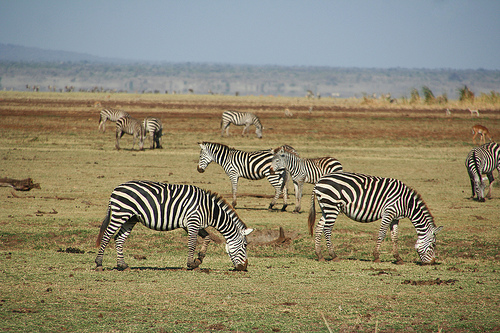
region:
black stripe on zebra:
[108, 211, 130, 222]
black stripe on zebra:
[111, 191, 148, 226]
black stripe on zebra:
[210, 202, 221, 229]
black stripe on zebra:
[218, 210, 225, 230]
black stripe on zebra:
[321, 204, 338, 211]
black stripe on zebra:
[316, 193, 341, 208]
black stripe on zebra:
[314, 180, 336, 201]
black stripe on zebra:
[406, 190, 414, 215]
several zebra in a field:
[46, 69, 468, 299]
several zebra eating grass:
[73, 77, 467, 304]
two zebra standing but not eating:
[158, 122, 388, 229]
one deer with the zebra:
[466, 108, 498, 167]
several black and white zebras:
[71, 97, 485, 288]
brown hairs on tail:
[305, 205, 319, 238]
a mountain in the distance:
[11, 38, 120, 95]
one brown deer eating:
[463, 119, 498, 156]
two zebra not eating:
[193, 128, 361, 239]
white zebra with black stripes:
[80, 167, 286, 294]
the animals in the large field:
[95, 106, 496, 268]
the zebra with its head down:
[307, 170, 442, 264]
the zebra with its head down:
[220, 109, 262, 139]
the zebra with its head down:
[465, 143, 499, 202]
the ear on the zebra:
[240, 228, 255, 235]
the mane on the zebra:
[202, 187, 247, 229]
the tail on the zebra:
[94, 193, 111, 248]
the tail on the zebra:
[306, 184, 315, 237]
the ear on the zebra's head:
[432, 225, 443, 235]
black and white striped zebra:
[93, 168, 257, 280]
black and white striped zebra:
[135, 103, 165, 148]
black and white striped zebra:
[78, 83, 124, 137]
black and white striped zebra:
[195, 99, 274, 143]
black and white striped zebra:
[189, 133, 304, 192]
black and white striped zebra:
[457, 116, 499, 188]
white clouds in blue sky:
[26, 15, 63, 41]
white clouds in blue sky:
[364, 6, 430, 60]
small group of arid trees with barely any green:
[407, 81, 476, 106]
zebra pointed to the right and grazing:
[305, 168, 440, 265]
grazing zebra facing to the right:
[92, 177, 254, 275]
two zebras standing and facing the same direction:
[193, 138, 343, 210]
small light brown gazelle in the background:
[467, 121, 495, 146]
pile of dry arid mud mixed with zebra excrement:
[246, 226, 295, 247]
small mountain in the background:
[0, 38, 152, 61]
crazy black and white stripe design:
[325, 175, 360, 205]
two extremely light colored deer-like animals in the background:
[440, 105, 480, 115]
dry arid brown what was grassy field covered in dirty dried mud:
[0, 96, 499, 148]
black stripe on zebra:
[111, 200, 131, 217]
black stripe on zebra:
[109, 190, 140, 217]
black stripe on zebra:
[112, 185, 152, 229]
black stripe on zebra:
[123, 180, 161, 232]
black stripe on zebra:
[136, 178, 166, 228]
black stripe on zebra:
[316, 183, 346, 206]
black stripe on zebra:
[326, 174, 361, 214]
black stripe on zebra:
[406, 188, 416, 220]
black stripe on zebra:
[210, 202, 220, 222]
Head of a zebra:
[224, 218, 252, 273]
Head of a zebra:
[413, 220, 443, 265]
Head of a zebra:
[191, 138, 213, 170]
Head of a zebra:
[264, 142, 291, 179]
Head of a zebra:
[111, 114, 126, 140]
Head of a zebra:
[253, 117, 266, 138]